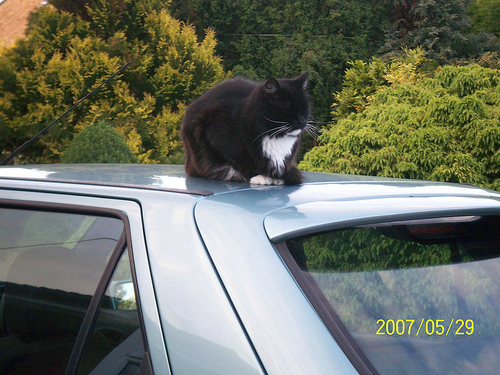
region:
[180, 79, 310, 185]
A black cat with a white chest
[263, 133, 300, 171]
White fur on the chest of a cat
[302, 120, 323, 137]
White whiskers on a cat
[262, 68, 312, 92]
Ears on the top of a cat's head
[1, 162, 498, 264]
Roof of a light blue car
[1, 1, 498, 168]
Green trees in the distance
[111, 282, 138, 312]
Side mirror on the opposite side of a car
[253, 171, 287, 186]
Front paws of a cat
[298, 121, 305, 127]
Black nose on a black cat's face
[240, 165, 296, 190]
The cat has white paws.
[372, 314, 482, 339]
Date the photo was taken.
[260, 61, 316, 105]
The cat has two ears.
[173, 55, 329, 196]
This cat is named Dice.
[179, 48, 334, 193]
The cat is named Oreo.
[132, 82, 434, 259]
a cat on a car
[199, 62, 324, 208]
a cat that is outside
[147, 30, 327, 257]
a black cat outside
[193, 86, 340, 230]
a black cat on a car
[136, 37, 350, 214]
a black cat sitting outside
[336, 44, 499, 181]
trees with green leaves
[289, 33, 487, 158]
leaves on the tree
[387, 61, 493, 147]
green leaves on the tree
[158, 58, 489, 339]
a black and whtie cat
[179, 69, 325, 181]
A black and white cat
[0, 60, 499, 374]
A gray saloon car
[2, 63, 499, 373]
The cat on the car roof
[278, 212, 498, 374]
The car's rear windscreen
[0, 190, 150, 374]
The car's side door screen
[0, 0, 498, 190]
The thick background vegetation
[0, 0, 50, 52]
The brown partially blocked buildings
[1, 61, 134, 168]
The car's dark radio antenna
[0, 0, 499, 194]
The sun glowing vegetation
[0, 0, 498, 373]
A gray car opposite the woods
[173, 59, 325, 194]
A cat in the foreground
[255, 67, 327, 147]
Cat's eyes are closed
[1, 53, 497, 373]
Cat is on a car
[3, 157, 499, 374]
A car in the foreground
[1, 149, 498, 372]
The car is silver in color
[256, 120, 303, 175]
Fur under the cat's mouth is white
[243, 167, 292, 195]
Cat's paws are white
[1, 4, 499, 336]
Bushes in the background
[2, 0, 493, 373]
Photo was taken in the daytime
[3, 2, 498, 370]
Photo was taken outdoors